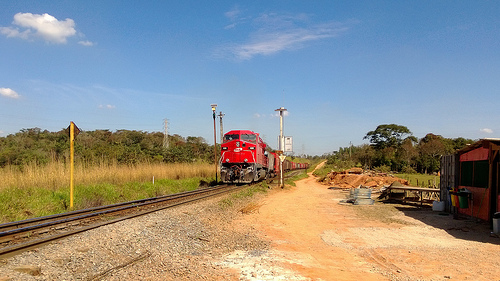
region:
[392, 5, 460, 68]
this is the sky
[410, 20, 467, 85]
the sky is blue in color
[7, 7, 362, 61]
the sky has some clouds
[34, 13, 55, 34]
the clouds are white in color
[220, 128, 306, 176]
this is a train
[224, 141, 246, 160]
the train is red in color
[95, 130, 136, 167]
these are some trees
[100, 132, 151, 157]
these are tree leaves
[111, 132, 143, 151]
the leaves are green in color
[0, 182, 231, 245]
this is a railway line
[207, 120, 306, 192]
red train coming down tracks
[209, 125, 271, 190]
front car of the train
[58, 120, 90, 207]
yellow pole by train tracks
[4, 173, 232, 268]
train tracks ahead of train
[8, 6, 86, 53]
white cloud on the left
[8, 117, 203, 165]
stand of trees on left side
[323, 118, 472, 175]
stand of trees on right side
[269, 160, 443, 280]
patch of dirt beside tracks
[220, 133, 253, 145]
front windows of train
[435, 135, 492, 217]
building by train tracks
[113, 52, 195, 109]
A blue sky above the train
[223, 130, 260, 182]
The front of the red train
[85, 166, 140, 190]
Tall grass by the train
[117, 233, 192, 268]
Gravel by the train tracks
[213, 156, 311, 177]
A red train on the tracks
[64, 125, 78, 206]
A yellow sign post by the train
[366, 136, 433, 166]
Green trees behind the train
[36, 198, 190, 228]
Train tracks in front of the train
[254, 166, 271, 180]
The wheels of the train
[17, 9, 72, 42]
A white cloud in the sky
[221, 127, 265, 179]
the train is in motion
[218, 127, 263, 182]
the train is red in color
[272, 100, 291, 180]
this is a post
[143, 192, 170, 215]
this is the rail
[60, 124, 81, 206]
the pole is yellow in color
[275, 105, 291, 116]
the light is off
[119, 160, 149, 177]
the grass are tall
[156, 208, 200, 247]
small stones are beside the rail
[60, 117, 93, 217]
A sign post pole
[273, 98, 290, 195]
A sign post pole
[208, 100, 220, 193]
A sign post pole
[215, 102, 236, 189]
A sign post pole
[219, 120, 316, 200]
This is a red train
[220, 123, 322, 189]
This is a train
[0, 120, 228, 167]
This is a forest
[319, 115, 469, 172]
This is a forest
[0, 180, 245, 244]
This is a railway line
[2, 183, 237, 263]
A rusty railway line